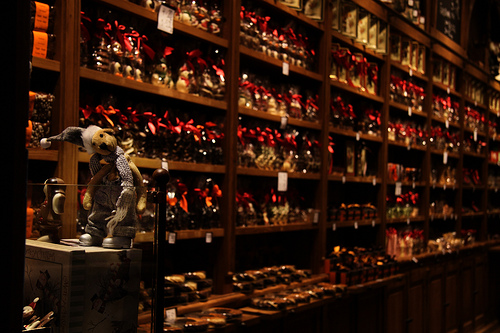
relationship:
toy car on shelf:
[247, 298, 286, 317] [225, 271, 326, 302]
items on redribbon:
[212, 133, 218, 160] [265, 129, 272, 140]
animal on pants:
[39, 125, 147, 249] [83, 180, 138, 240]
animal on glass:
[39, 125, 147, 249] [27, 177, 161, 330]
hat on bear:
[37, 118, 103, 150] [80, 123, 145, 248]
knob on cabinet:
[334, 287, 356, 318] [338, 283, 415, 331]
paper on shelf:
[155, 0, 180, 35] [7, 5, 498, 331]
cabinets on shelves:
[358, 250, 497, 328] [18, 0, 497, 242]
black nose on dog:
[99, 143, 108, 150] [51, 122, 147, 244]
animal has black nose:
[39, 125, 147, 249] [99, 143, 108, 150]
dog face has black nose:
[83, 125, 121, 162] [99, 140, 109, 150]